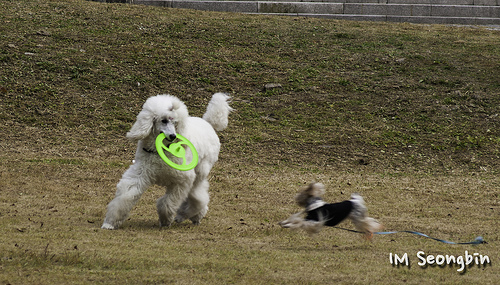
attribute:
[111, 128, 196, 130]
dog — carrying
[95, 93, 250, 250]
dog — white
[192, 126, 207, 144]
color — white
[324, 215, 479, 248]
rope — blue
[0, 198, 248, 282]
vegetation — dry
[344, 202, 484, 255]
leash — blue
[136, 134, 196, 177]
frisbee — lime green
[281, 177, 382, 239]
terrier — tricolor 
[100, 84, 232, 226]
dog — white, HAIRY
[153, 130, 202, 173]
frisbee — green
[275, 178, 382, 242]
dog — small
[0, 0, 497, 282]
grass — patchy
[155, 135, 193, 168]
frisbee — NEON, GREEN, CIRCLE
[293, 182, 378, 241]
dog — BLURRY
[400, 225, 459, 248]
leash — BLUE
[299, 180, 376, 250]
dog — BROWN, WHITE, BLACK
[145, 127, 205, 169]
frisbee — GREEN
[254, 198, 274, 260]
grass — GREEN, BROWN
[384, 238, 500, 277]
text — some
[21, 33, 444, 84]
grass — green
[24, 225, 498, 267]
grass — brown, dead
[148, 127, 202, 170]
frisbee — green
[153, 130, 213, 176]
frisbee — green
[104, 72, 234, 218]
dog — white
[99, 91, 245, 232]
dog — white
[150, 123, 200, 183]
frisbee — green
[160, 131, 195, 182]
frisbee — green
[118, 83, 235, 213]
dog — white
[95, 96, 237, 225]
dog — white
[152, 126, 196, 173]
frisbee — green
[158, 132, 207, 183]
frisbee — green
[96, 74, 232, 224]
dog — white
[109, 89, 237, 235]
dog — white